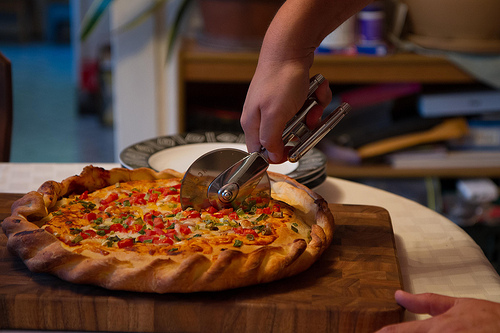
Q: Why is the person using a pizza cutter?
A: To slice the pizza.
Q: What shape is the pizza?
A: Round.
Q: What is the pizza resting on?
A: A cutting board.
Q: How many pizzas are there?
A: 1.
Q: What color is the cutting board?
A: Brown.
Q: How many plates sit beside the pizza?
A: 3.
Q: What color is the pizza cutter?
A: Silver.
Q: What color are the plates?
A: White with black.